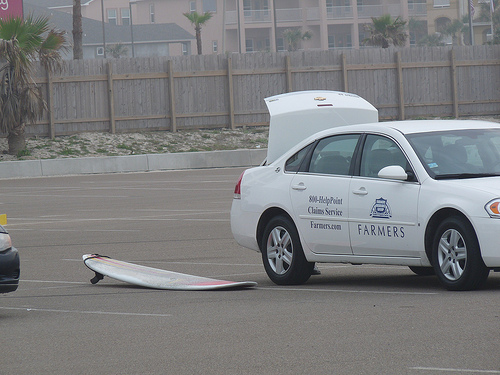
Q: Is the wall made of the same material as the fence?
A: No, the wall is made of concrete and the fence is made of wood.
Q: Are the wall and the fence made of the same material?
A: No, the wall is made of concrete and the fence is made of wood.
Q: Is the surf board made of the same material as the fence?
A: No, the surf board is made of plastic and the fence is made of wood.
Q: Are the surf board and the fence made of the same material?
A: No, the surf board is made of plastic and the fence is made of wood.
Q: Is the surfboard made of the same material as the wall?
A: No, the surfboard is made of plastic and the wall is made of concrete.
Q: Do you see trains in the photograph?
A: No, there are no trains.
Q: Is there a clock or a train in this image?
A: No, there are no trains or clocks.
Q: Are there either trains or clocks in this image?
A: No, there are no trains or clocks.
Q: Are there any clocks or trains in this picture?
A: No, there are no trains or clocks.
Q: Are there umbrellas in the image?
A: No, there are no umbrellas.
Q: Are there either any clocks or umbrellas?
A: No, there are no umbrellas or clocks.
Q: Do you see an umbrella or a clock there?
A: No, there are no umbrellas or clocks.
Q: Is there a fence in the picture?
A: Yes, there is a fence.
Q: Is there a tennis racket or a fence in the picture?
A: Yes, there is a fence.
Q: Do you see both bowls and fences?
A: No, there is a fence but no bowls.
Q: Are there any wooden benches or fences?
A: Yes, there is a wood fence.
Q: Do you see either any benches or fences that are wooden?
A: Yes, the fence is wooden.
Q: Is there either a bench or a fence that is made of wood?
A: Yes, the fence is made of wood.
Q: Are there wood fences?
A: Yes, there is a wood fence.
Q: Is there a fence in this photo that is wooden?
A: Yes, there is a fence that is wooden.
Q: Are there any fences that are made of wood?
A: Yes, there is a fence that is made of wood.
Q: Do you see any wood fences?
A: Yes, there is a fence that is made of wood.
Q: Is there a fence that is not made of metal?
A: Yes, there is a fence that is made of wood.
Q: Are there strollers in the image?
A: No, there are no strollers.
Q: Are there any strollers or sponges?
A: No, there are no strollers or sponges.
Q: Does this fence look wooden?
A: Yes, the fence is wooden.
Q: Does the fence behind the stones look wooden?
A: Yes, the fence is wooden.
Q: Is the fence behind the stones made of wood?
A: Yes, the fence is made of wood.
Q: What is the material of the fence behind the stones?
A: The fence is made of wood.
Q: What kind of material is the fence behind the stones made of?
A: The fence is made of wood.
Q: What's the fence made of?
A: The fence is made of wood.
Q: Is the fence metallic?
A: No, the fence is wooden.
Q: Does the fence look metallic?
A: No, the fence is wooden.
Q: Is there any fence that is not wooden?
A: No, there is a fence but it is wooden.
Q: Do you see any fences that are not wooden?
A: No, there is a fence but it is wooden.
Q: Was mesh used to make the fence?
A: No, the fence is made of wood.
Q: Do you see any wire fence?
A: No, there is a fence but it is made of wood.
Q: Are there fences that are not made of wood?
A: No, there is a fence but it is made of wood.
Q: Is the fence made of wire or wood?
A: The fence is made of wood.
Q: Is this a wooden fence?
A: Yes, this is a wooden fence.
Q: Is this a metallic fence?
A: No, this is a wooden fence.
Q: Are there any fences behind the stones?
A: Yes, there is a fence behind the stones.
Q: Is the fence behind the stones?
A: Yes, the fence is behind the stones.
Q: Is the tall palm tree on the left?
A: Yes, the palm tree is on the left of the image.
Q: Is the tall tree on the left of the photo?
A: Yes, the palm tree is on the left of the image.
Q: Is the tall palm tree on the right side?
A: No, the palm tree is on the left of the image.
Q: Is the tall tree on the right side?
A: No, the palm tree is on the left of the image.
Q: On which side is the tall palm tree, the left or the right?
A: The palm is on the left of the image.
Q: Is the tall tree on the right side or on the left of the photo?
A: The palm is on the left of the image.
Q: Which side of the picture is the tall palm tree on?
A: The palm is on the left of the image.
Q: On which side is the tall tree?
A: The palm is on the left of the image.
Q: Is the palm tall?
A: Yes, the palm is tall.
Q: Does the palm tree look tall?
A: Yes, the palm tree is tall.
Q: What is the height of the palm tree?
A: The palm tree is tall.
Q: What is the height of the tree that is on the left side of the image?
A: The palm tree is tall.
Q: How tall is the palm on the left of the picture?
A: The palm tree is tall.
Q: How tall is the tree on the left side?
A: The palm tree is tall.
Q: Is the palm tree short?
A: No, the palm tree is tall.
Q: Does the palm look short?
A: No, the palm is tall.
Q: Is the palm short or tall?
A: The palm is tall.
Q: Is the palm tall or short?
A: The palm is tall.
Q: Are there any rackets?
A: No, there are no rackets.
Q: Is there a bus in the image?
A: No, there are no buses.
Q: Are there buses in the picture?
A: No, there are no buses.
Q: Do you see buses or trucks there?
A: No, there are no buses or trucks.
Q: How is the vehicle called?
A: The vehicle is a car.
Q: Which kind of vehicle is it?
A: The vehicle is a car.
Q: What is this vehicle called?
A: This is a car.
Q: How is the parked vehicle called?
A: The vehicle is a car.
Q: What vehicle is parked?
A: The vehicle is a car.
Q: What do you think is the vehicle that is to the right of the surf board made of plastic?
A: The vehicle is a car.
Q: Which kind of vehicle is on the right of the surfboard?
A: The vehicle is a car.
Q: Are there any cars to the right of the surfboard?
A: Yes, there is a car to the right of the surfboard.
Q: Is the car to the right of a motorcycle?
A: No, the car is to the right of a surfboard.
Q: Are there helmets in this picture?
A: No, there are no helmets.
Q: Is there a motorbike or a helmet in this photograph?
A: No, there are no helmets or motorcycles.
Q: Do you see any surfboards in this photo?
A: Yes, there is a surfboard.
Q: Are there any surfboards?
A: Yes, there is a surfboard.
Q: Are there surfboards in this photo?
A: Yes, there is a surfboard.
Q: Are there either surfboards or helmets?
A: Yes, there is a surfboard.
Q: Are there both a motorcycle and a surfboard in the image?
A: No, there is a surfboard but no motorcycles.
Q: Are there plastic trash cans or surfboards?
A: Yes, there is a plastic surfboard.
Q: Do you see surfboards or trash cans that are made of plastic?
A: Yes, the surfboard is made of plastic.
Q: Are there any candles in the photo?
A: No, there are no candles.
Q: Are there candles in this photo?
A: No, there are no candles.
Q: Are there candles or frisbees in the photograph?
A: No, there are no candles or frisbees.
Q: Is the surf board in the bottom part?
A: Yes, the surf board is in the bottom of the image.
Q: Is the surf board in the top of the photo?
A: No, the surf board is in the bottom of the image.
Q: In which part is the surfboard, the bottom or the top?
A: The surfboard is in the bottom of the image.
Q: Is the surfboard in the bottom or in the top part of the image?
A: The surfboard is in the bottom of the image.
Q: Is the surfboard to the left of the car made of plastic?
A: Yes, the surfboard is made of plastic.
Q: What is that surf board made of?
A: The surf board is made of plastic.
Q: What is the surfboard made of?
A: The surf board is made of plastic.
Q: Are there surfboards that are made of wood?
A: No, there is a surfboard but it is made of plastic.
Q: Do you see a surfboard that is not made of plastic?
A: No, there is a surfboard but it is made of plastic.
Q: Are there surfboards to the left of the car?
A: Yes, there is a surfboard to the left of the car.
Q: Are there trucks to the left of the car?
A: No, there is a surfboard to the left of the car.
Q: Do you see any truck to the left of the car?
A: No, there is a surfboard to the left of the car.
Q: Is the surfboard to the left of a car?
A: Yes, the surfboard is to the left of a car.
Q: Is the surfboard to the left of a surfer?
A: No, the surfboard is to the left of a car.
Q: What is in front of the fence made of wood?
A: The stones are in front of the fence.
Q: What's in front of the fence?
A: The stones are in front of the fence.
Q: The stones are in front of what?
A: The stones are in front of the fence.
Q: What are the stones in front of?
A: The stones are in front of the fence.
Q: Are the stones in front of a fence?
A: Yes, the stones are in front of a fence.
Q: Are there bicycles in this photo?
A: No, there are no bicycles.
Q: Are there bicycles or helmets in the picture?
A: No, there are no bicycles or helmets.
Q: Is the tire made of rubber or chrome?
A: The tire is made of rubber.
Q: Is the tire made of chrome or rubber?
A: The tire is made of rubber.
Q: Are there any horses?
A: No, there are no horses.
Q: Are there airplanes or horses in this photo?
A: No, there are no horses or airplanes.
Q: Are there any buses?
A: No, there are no buses.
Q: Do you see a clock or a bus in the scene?
A: No, there are no buses or clocks.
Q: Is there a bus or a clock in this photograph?
A: No, there are no buses or clocks.